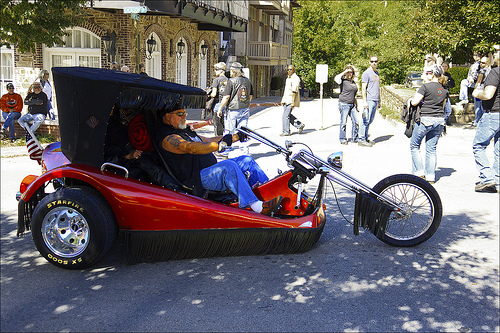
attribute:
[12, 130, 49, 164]
us flag — small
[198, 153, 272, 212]
jeans — blue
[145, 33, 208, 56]
lanterns — black 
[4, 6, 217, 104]
wall — stone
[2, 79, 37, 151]
woman — sitting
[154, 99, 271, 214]
man — sitting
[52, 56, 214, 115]
roof — canopy , black 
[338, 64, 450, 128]
wall — low, brick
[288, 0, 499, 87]
trees — green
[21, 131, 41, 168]
flag — small 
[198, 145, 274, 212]
pants — blue , denim  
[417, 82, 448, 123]
shirt — black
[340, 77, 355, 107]
shirt — black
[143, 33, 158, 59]
street lamp — decorative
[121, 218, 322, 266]
fringe — black 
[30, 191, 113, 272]
tire — black , large 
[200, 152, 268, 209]
jeans — blue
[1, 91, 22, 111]
shirt — red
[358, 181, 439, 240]
wheel — wire spoked